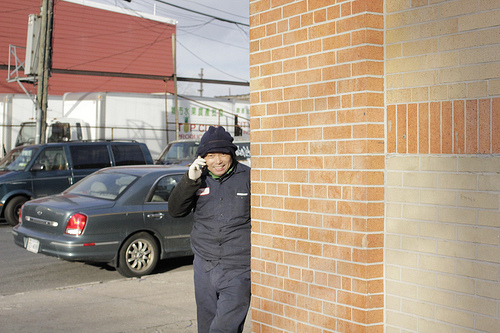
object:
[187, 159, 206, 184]
glove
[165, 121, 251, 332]
man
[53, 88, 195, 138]
wall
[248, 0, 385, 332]
pillar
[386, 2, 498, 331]
wall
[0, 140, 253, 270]
vehicles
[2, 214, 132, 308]
road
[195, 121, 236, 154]
cap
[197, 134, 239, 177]
head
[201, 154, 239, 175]
face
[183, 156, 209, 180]
hand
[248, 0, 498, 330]
building